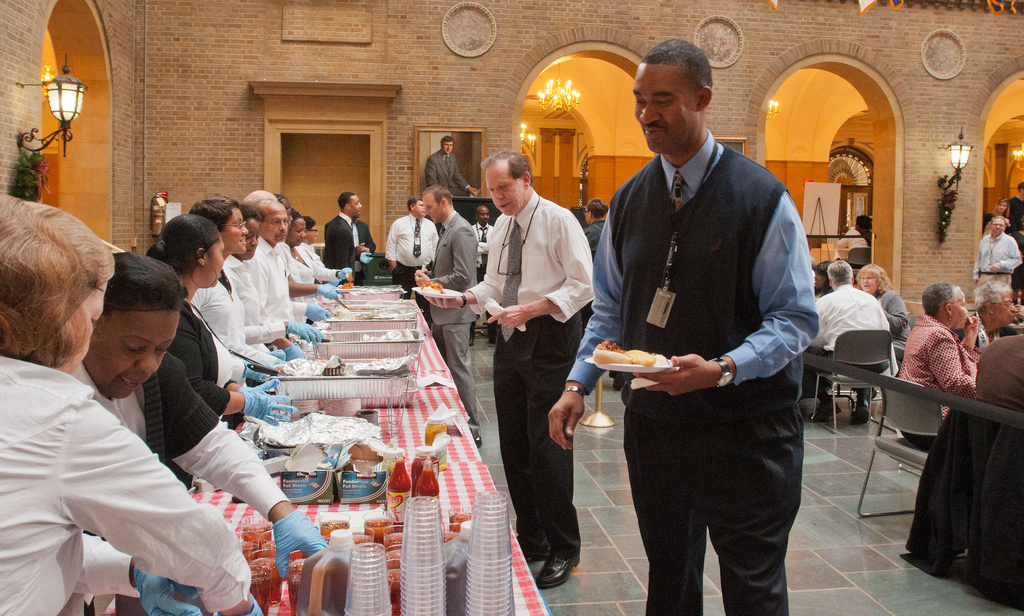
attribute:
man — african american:
[549, 47, 815, 609]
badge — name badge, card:
[644, 286, 674, 328]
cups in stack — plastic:
[342, 499, 516, 611]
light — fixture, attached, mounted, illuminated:
[21, 70, 85, 156]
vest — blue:
[609, 172, 789, 415]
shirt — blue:
[570, 154, 829, 376]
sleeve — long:
[737, 200, 819, 376]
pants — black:
[619, 393, 810, 611]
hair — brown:
[483, 159, 532, 182]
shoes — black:
[527, 545, 573, 589]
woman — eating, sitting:
[904, 280, 988, 393]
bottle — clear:
[386, 465, 403, 526]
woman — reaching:
[97, 258, 285, 526]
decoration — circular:
[439, 14, 505, 66]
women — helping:
[5, 217, 322, 611]